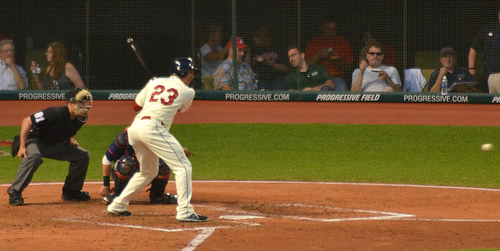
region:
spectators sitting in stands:
[3, 17, 495, 95]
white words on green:
[2, 93, 497, 101]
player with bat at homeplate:
[108, 37, 198, 220]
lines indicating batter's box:
[252, 201, 414, 223]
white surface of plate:
[217, 212, 264, 221]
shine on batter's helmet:
[170, 54, 198, 72]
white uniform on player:
[107, 75, 200, 217]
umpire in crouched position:
[8, 86, 92, 206]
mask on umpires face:
[72, 88, 93, 121]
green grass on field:
[2, 123, 499, 185]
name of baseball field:
[307, 92, 386, 102]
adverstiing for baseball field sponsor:
[218, 91, 292, 101]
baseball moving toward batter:
[479, 140, 493, 152]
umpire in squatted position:
[6, 85, 94, 206]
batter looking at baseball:
[107, 36, 214, 220]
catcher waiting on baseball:
[100, 113, 191, 205]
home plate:
[217, 213, 264, 220]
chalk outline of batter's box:
[48, 201, 413, 232]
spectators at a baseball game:
[196, 19, 498, 90]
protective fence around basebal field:
[0, 0, 499, 96]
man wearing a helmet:
[107, 25, 222, 226]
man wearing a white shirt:
[118, 21, 210, 247]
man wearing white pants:
[110, 20, 227, 240]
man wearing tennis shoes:
[105, 27, 225, 229]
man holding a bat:
[105, 26, 211, 236]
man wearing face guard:
[1, 70, 93, 221]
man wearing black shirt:
[0, 70, 90, 210]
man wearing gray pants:
[10, 77, 90, 218]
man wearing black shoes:
[0, 70, 92, 206]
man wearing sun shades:
[345, 29, 395, 106]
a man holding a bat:
[110, 40, 212, 110]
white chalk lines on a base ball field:
[185, 193, 403, 248]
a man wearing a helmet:
[164, 42, 203, 92]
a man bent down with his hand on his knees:
[21, 86, 101, 168]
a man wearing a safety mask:
[60, 86, 100, 145]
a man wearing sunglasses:
[365, 32, 390, 62]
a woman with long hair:
[40, 32, 67, 93]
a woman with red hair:
[33, 39, 68, 87]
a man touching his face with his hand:
[0, 36, 29, 86]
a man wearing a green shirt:
[285, 41, 322, 90]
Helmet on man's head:
[168, 50, 203, 77]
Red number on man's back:
[151, 78, 178, 108]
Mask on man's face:
[55, 81, 90, 116]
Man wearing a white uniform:
[102, 48, 217, 228]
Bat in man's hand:
[108, 30, 195, 106]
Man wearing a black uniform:
[7, 88, 104, 212]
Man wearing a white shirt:
[346, 38, 407, 103]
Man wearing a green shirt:
[272, 36, 349, 95]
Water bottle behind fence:
[436, 72, 454, 97]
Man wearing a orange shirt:
[295, 19, 353, 94]